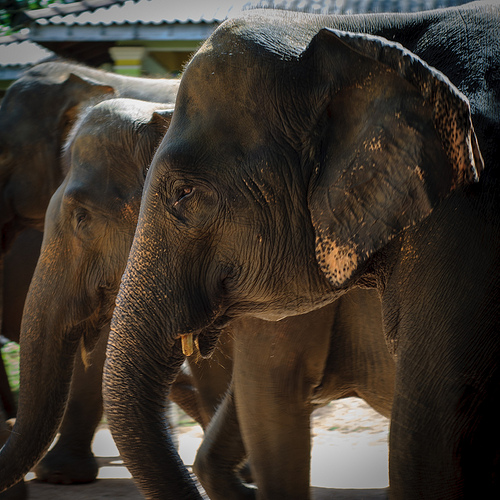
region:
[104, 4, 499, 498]
1st elephant that can be seen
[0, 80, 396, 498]
2nd elephant that can be seen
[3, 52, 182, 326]
3rd elephant that can be seen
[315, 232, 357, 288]
dirt on first elephants ear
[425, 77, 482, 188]
dirt on first elephants ear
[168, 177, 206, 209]
1st elephants brown eye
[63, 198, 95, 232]
2nd elephants eye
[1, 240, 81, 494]
2nd elephants trunk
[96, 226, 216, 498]
1st elephants trunk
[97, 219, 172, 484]
dirt on first elephants trunk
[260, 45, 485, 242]
ear of the elephant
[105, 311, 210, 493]
trunk of the elephant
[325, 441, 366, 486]
ground under the elephant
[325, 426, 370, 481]
light hitting the ground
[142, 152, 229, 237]
eye of the elephant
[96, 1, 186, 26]
roof in the background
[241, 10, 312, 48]
light hitting the head of the elephant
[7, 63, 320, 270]
a few different elephants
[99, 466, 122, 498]
shadow on the ground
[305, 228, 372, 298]
bottom of the ear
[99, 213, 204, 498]
grey elephant trunk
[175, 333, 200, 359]
short white tusk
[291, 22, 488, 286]
grey and pink elephant ear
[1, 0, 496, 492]
group of grey elephant standing on ground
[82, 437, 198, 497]
elephant shadow on ground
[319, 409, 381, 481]
tan dirt ground beneath elephants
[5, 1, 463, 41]
grey house roof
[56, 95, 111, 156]
hair on elephant head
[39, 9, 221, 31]
ridged house roof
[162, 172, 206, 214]
one elephant eye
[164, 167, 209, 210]
part 0of an eye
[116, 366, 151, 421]
part of a trunk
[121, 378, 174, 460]
part of a trunk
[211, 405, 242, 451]
part of a trunk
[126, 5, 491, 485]
this is an elephant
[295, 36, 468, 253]
this is the ear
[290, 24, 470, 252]
the ear is big in size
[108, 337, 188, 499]
this is the trunk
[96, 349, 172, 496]
the trunk is long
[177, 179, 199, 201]
this is the eye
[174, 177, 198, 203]
the eye is open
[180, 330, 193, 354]
the tusk is small in size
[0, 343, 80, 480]
the trunk is coiled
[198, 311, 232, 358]
this is the mouth